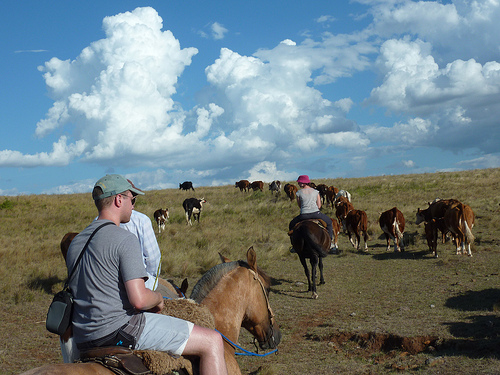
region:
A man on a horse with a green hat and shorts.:
[62, 173, 228, 373]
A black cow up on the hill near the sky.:
[178, 180, 194, 192]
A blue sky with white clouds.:
[0, 2, 499, 192]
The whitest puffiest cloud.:
[37, 7, 199, 156]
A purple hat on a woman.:
[295, 174, 311, 185]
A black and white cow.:
[180, 196, 206, 225]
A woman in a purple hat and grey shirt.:
[288, 174, 336, 251]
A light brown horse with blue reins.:
[21, 245, 280, 373]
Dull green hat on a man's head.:
[90, 173, 146, 201]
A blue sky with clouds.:
[1, 0, 498, 183]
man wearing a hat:
[92, 165, 147, 221]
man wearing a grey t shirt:
[51, 225, 142, 329]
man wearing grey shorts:
[125, 308, 200, 362]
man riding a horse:
[45, 160, 299, 369]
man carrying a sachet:
[33, 268, 88, 345]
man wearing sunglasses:
[113, 188, 142, 208]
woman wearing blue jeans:
[285, 208, 337, 243]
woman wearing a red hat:
[293, 168, 310, 190]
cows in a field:
[168, 173, 216, 224]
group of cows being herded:
[179, 168, 473, 268]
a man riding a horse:
[88, 172, 282, 374]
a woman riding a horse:
[291, 175, 326, 249]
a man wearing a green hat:
[93, 172, 140, 203]